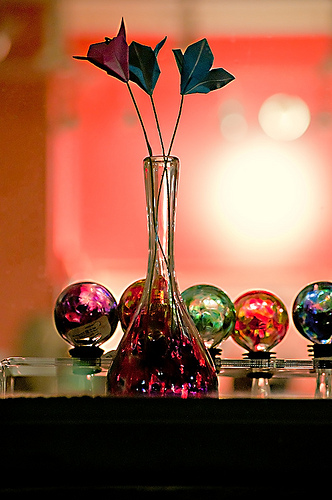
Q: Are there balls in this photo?
A: Yes, there is a ball.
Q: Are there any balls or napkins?
A: Yes, there is a ball.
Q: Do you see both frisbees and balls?
A: No, there is a ball but no frisbees.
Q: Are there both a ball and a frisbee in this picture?
A: No, there is a ball but no frisbees.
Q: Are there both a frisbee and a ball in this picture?
A: No, there is a ball but no frisbees.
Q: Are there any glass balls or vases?
A: Yes, there is a glass ball.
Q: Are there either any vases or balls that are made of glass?
A: Yes, the ball is made of glass.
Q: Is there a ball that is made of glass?
A: Yes, there is a ball that is made of glass.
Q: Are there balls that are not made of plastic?
A: Yes, there is a ball that is made of glass.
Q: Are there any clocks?
A: No, there are no clocks.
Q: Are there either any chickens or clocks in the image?
A: No, there are no clocks or chickens.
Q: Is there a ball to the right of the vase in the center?
A: Yes, there is a ball to the right of the vase.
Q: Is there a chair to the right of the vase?
A: No, there is a ball to the right of the vase.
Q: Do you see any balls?
A: Yes, there is a ball.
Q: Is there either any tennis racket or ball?
A: Yes, there is a ball.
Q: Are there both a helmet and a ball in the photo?
A: No, there is a ball but no helmets.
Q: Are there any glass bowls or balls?
A: Yes, there is a glass ball.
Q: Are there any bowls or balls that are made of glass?
A: Yes, the ball is made of glass.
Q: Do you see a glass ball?
A: Yes, there is a ball that is made of glass.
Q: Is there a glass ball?
A: Yes, there is a ball that is made of glass.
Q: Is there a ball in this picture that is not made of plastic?
A: Yes, there is a ball that is made of glass.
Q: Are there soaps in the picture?
A: No, there are no soaps.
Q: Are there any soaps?
A: No, there are no soaps.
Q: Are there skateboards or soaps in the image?
A: No, there are no soaps or skateboards.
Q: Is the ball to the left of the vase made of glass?
A: Yes, the ball is made of glass.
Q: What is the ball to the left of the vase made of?
A: The ball is made of glass.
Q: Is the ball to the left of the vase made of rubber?
A: No, the ball is made of glass.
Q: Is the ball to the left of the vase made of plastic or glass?
A: The ball is made of glass.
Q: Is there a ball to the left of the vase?
A: Yes, there is a ball to the left of the vase.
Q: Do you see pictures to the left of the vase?
A: No, there is a ball to the left of the vase.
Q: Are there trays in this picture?
A: No, there are no trays.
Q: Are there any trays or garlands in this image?
A: No, there are no trays or garlands.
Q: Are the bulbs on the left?
A: Yes, the bulbs are on the left of the image.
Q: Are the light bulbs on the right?
A: No, the light bulbs are on the left of the image.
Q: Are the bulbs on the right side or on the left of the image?
A: The bulbs are on the left of the image.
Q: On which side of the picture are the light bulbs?
A: The light bulbs are on the left of the image.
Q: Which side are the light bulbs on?
A: The light bulbs are on the left of the image.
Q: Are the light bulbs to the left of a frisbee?
A: No, the light bulbs are to the left of the ball.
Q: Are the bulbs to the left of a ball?
A: Yes, the bulbs are to the left of a ball.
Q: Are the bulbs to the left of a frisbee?
A: No, the bulbs are to the left of a ball.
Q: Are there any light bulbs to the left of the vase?
A: Yes, there are light bulbs to the left of the vase.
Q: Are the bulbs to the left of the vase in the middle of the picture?
A: Yes, the bulbs are to the left of the vase.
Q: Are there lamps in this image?
A: No, there are no lamps.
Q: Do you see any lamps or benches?
A: No, there are no lamps or benches.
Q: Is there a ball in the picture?
A: Yes, there is a ball.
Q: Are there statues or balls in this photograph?
A: Yes, there is a ball.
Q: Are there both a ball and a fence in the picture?
A: No, there is a ball but no fences.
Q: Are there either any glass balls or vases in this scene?
A: Yes, there is a glass ball.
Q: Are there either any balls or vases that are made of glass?
A: Yes, the ball is made of glass.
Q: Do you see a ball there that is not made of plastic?
A: Yes, there is a ball that is made of glass.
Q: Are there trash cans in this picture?
A: No, there are no trash cans.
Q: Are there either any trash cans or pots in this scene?
A: No, there are no trash cans or pots.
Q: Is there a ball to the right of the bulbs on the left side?
A: Yes, there is a ball to the right of the light bulbs.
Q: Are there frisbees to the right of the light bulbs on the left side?
A: No, there is a ball to the right of the light bulbs.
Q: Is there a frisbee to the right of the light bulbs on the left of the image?
A: No, there is a ball to the right of the light bulbs.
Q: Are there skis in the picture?
A: No, there are no skis.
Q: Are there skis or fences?
A: No, there are no skis or fences.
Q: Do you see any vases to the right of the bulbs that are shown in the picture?
A: Yes, there is a vase to the right of the bulbs.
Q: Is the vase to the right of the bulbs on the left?
A: Yes, the vase is to the right of the light bulbs.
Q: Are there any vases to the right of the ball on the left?
A: Yes, there is a vase to the right of the ball.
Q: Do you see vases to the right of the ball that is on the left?
A: Yes, there is a vase to the right of the ball.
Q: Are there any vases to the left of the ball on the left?
A: No, the vase is to the right of the ball.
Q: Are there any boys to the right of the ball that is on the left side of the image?
A: No, there is a vase to the right of the ball.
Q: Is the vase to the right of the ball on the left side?
A: Yes, the vase is to the right of the ball.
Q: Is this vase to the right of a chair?
A: No, the vase is to the right of the ball.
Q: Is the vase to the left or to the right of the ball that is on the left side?
A: The vase is to the right of the ball.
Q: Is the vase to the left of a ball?
A: Yes, the vase is to the left of a ball.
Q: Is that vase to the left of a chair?
A: No, the vase is to the left of a ball.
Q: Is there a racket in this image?
A: No, there are no rackets.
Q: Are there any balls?
A: Yes, there is a ball.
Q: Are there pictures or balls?
A: Yes, there is a ball.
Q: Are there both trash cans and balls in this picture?
A: No, there is a ball but no trash cans.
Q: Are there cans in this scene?
A: No, there are no cans.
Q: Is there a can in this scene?
A: No, there are no cans.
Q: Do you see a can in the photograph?
A: No, there are no cans.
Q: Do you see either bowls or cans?
A: No, there are no cans or bowls.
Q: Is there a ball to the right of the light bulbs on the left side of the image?
A: Yes, there is a ball to the right of the bulbs.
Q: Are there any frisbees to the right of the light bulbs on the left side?
A: No, there is a ball to the right of the light bulbs.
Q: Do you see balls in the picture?
A: Yes, there is a ball.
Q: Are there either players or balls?
A: Yes, there is a ball.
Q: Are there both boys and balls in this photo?
A: No, there is a ball but no boys.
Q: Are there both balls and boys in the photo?
A: No, there is a ball but no boys.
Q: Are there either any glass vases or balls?
A: Yes, there is a glass ball.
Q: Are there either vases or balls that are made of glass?
A: Yes, the ball is made of glass.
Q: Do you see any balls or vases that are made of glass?
A: Yes, the ball is made of glass.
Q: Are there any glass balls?
A: Yes, there is a ball that is made of glass.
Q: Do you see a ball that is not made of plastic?
A: Yes, there is a ball that is made of glass.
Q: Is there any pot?
A: No, there are no pots.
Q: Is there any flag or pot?
A: No, there are no pots or flags.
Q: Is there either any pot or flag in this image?
A: No, there are no pots or flags.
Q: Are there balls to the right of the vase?
A: Yes, there is a ball to the right of the vase.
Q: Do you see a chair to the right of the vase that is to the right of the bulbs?
A: No, there is a ball to the right of the vase.